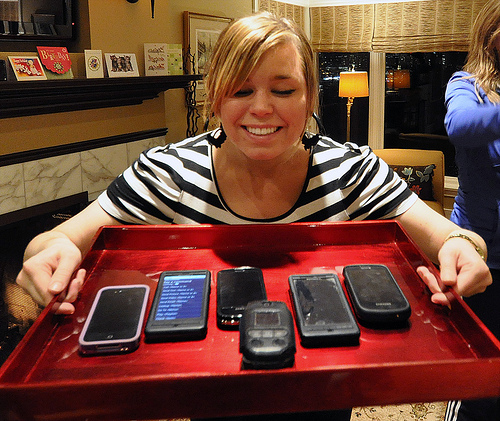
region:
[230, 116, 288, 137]
Smiling mouth of young lady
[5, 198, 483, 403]
Red tray holding different kinds of phones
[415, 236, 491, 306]
Left hand of young lady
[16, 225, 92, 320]
Right hand of young lady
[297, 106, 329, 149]
Black earrings in left ear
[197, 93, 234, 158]
Black earrings in right ear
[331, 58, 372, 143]
Pole lamp with yellow shade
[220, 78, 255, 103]
Right eye of young lady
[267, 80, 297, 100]
Left eye of young lady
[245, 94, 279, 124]
Nose of young lady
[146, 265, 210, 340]
black phone on red tray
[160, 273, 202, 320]
blue and white display on a phone screen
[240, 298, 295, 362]
closed flip phone on a red tray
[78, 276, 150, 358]
white rim phone on a red tray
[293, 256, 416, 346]
two black phones on a red tray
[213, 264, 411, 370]
four black phones on a red tray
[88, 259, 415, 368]
six black phones on a red tray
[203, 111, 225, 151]
black chandelier earrings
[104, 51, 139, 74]
photo containing animals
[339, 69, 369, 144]
lamp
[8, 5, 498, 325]
person holding a red tray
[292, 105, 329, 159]
earring in a persons ear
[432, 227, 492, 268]
watch on a persons wrist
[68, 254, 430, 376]
phones on a red tray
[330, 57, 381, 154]
lamp near a window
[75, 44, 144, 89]
cards on a mantle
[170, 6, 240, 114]
picture on a wall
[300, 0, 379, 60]
blind on a window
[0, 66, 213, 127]
mantle on a wall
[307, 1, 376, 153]
window in a room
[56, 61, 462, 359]
woman holding red tray with cell phones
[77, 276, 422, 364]
six cell phones in photo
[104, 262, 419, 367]
one cell phone turned on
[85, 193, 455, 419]
six phones on red tray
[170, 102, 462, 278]
woman in black and white shirt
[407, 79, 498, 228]
someone in blue shirt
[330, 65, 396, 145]
one lamp in photo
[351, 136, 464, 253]
one brown chair with black flower pillow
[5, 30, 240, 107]
cards on mantle in photo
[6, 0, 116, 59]
mirror in photo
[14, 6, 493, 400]
young woman holding a tray of cellphones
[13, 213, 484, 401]
a red tray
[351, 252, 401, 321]
a samsung smartphone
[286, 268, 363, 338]
a rectangular smartphone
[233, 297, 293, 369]
an old flip phone cell phone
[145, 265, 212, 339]
a smartphone with the screen lit up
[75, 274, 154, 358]
an iphone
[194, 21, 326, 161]
a young woman with her eyes closed smiling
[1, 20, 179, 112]
birthday cards above a fireplace mantel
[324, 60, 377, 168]
a lamp in front of a window